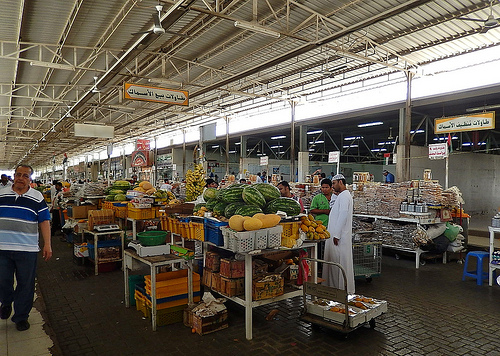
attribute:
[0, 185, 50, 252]
shirt — striped, blue and white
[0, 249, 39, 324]
denim pants — dark, blue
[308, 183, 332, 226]
green shirt — bright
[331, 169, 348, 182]
cap — white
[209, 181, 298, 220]
watermelon — green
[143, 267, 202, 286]
crate — yellow, plastic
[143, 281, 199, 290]
crate — yellow, plastic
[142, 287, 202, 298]
crate — yellow, plastic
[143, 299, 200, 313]
crate — yellow, plastic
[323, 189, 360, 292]
white robe — long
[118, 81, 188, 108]
sign — white and yellow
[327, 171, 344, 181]
cap — white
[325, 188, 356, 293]
robe — white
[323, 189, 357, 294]
gown — white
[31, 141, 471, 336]
market — large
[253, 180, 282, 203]
watermelon — bright , green , striped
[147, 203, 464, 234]
stool — blue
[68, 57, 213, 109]
sign — arabic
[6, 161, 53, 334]
man — walking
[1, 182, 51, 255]
striped shirt — striped 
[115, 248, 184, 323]
table — small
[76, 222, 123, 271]
table — small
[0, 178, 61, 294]
shirt — white, blue, grey, short-sleeved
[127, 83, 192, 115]
sign — orange, white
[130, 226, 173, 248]
bowl — green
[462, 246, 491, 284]
stool — big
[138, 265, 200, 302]
containers — orange, plastic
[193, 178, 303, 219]
watermelon — striped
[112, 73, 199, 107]
sign — arabic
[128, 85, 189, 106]
writing — black 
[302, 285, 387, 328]
packages — white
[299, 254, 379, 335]
cart — brown, metal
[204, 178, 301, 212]
watermelons — stacked